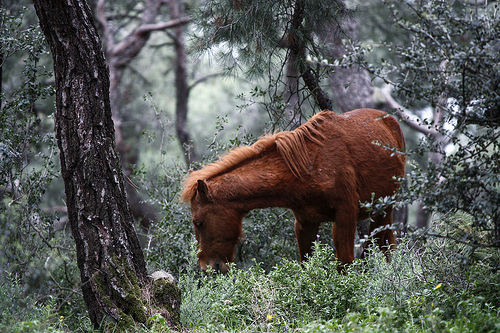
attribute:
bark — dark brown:
[32, 5, 151, 297]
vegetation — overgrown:
[141, 192, 498, 331]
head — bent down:
[143, 155, 263, 278]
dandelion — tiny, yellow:
[12, 279, 78, 331]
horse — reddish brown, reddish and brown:
[182, 100, 409, 287]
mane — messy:
[186, 106, 328, 179]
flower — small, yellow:
[265, 313, 272, 323]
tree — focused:
[41, 7, 167, 316]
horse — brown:
[177, 106, 405, 274]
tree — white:
[404, 81, 436, 242]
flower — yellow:
[248, 271, 329, 326]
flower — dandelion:
[427, 279, 446, 299]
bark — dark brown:
[37, 5, 185, 329]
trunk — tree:
[34, 4, 188, 328]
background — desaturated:
[4, 48, 494, 128]